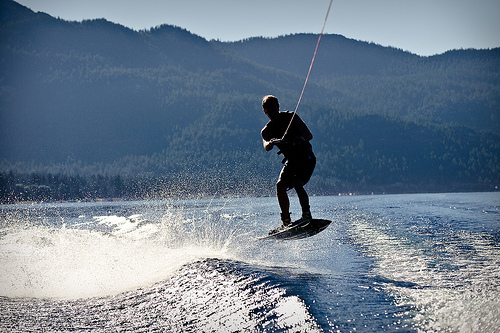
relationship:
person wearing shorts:
[253, 87, 322, 231] [274, 154, 322, 190]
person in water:
[253, 87, 322, 231] [2, 184, 498, 331]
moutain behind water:
[9, 6, 500, 195] [2, 184, 498, 331]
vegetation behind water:
[2, 6, 500, 192] [2, 184, 498, 331]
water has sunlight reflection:
[2, 184, 498, 331] [434, 201, 493, 213]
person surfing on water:
[253, 87, 322, 231] [2, 184, 498, 331]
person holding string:
[253, 87, 322, 231] [271, 4, 351, 151]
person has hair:
[253, 87, 322, 231] [260, 91, 284, 112]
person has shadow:
[253, 87, 322, 231] [349, 265, 453, 294]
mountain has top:
[9, 6, 500, 195] [5, 1, 74, 28]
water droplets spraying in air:
[140, 167, 306, 272] [4, 11, 499, 227]